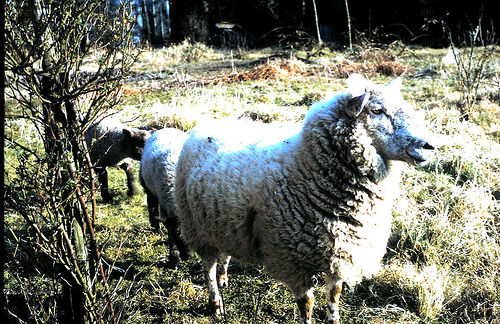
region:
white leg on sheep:
[194, 252, 228, 317]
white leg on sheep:
[214, 244, 234, 289]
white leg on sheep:
[295, 284, 317, 321]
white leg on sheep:
[321, 276, 341, 321]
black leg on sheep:
[163, 212, 188, 259]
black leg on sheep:
[141, 183, 160, 231]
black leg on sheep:
[91, 160, 113, 198]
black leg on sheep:
[119, 162, 135, 199]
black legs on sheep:
[94, 160, 140, 205]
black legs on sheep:
[141, 189, 190, 264]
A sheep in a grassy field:
[160, 62, 440, 319]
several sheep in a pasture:
[43, 59, 487, 318]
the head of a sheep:
[320, 73, 470, 198]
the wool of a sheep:
[204, 145, 306, 246]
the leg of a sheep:
[291, 271, 316, 322]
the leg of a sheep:
[318, 273, 364, 320]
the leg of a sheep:
[194, 244, 226, 319]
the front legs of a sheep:
[288, 265, 356, 322]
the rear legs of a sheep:
[184, 241, 245, 321]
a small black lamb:
[66, 104, 148, 211]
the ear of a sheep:
[346, 90, 373, 118]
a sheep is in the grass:
[124, 75, 439, 249]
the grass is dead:
[111, 252, 197, 312]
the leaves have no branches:
[40, 125, 149, 289]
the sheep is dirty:
[206, 114, 466, 316]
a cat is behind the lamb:
[91, 99, 171, 222]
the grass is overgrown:
[425, 168, 470, 263]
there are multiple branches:
[18, 161, 148, 313]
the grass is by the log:
[199, 46, 363, 174]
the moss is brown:
[241, 53, 343, 92]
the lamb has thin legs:
[187, 242, 276, 321]